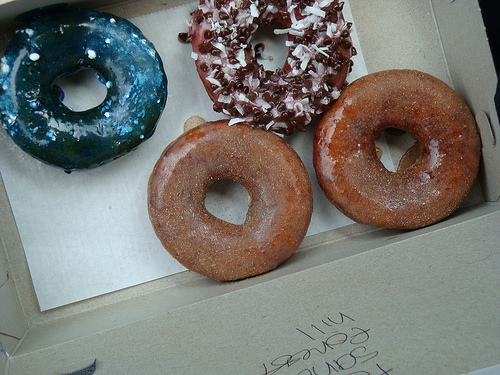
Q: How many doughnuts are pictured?
A: Four.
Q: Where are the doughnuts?
A: In a box.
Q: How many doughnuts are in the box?
A: 4.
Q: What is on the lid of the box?
A: Writing.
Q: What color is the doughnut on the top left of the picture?
A: Blue.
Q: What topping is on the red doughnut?
A: Coconut and chocolate chips.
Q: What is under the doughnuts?
A: Paper.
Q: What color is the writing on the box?
A: Black.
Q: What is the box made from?
A: Cardboard.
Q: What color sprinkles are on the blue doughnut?
A: White.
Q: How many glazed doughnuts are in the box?
A: 2.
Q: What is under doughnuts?
A: Parchment paper.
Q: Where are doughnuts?
A: Cardboard box.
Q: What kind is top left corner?
A: Blue doughnut with glaze.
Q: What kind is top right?
A: Chocolate with coconut.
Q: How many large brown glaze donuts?
A: 2.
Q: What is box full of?
A: Different colored donuts.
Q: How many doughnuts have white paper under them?
A: 4.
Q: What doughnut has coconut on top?
A: The one at the top right.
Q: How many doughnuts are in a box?
A: 4.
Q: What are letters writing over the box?
A: The types of doughnuts.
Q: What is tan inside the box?
A: 2 of the doughnuts.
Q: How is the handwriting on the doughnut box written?
A: Upside down and in pencil.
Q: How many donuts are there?
A: Four.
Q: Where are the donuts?
A: A box.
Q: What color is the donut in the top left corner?
A: Blue.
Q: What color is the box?
A: White.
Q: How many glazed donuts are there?
A: Two.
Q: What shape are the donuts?
A: Circles.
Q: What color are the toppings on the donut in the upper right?
A: Black and white.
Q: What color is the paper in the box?
A: White.